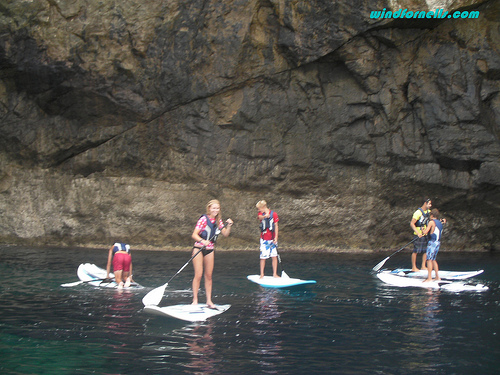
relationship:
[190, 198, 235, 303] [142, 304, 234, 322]
woman on board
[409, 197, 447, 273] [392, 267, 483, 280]
man on board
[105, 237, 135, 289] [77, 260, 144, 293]
person on board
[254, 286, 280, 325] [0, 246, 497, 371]
reflection in water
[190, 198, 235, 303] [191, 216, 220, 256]
woman wearing swimsuit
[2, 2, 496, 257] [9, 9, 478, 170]
cliff has crack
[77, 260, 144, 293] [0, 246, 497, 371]
board in water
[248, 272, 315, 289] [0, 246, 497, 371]
board in water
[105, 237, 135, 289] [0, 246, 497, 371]
person in water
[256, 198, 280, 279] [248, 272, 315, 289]
boy on board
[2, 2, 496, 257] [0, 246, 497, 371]
cliff near water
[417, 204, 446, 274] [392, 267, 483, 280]
person on board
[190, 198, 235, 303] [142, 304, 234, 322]
woman using board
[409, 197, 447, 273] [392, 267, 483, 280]
man using board